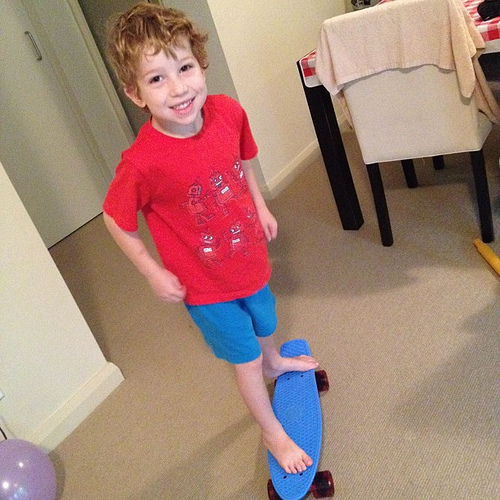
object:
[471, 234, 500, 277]
toy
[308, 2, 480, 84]
cloth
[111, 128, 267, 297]
shirt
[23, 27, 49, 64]
handle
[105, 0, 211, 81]
hair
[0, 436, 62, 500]
ball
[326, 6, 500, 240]
chair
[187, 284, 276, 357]
shorts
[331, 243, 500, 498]
floor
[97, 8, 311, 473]
boy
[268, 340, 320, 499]
skateboard